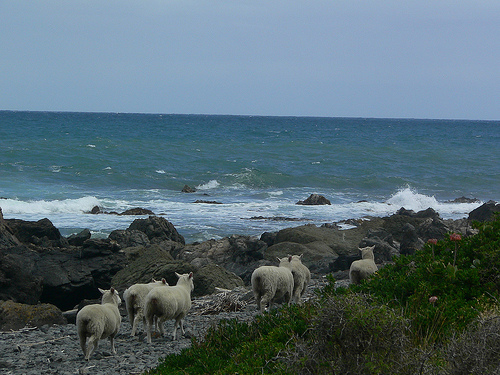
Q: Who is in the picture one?
A: No one.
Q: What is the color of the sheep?
A: White.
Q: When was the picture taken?
A: During the day.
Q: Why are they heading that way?
A: Looking for water.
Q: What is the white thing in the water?
A: Waves.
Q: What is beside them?
A: Bushes.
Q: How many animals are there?
A: 6.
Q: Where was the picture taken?
A: Near the ocean.